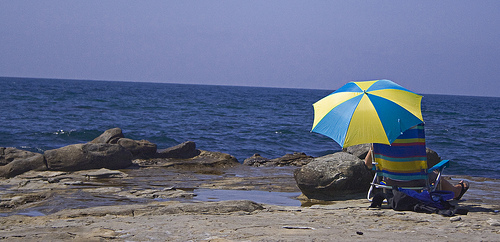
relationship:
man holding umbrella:
[373, 139, 444, 199] [310, 73, 430, 173]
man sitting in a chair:
[364, 139, 471, 203] [371, 118, 452, 213]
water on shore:
[192, 185, 303, 207] [14, 132, 336, 235]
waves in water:
[26, 83, 167, 125] [179, 88, 297, 141]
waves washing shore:
[26, 83, 167, 125] [0, 127, 500, 241]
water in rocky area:
[192, 185, 303, 207] [4, 127, 383, 236]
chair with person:
[361, 134, 444, 218] [400, 123, 487, 221]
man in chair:
[364, 139, 471, 203] [363, 131, 456, 231]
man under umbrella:
[364, 139, 471, 203] [309, 79, 421, 155]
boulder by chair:
[290, 145, 392, 210] [356, 110, 473, 235]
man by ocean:
[364, 139, 471, 203] [29, 80, 479, 161]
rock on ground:
[237, 152, 271, 167] [78, 116, 276, 242]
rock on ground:
[237, 152, 271, 167] [221, 137, 284, 181]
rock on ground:
[237, 152, 271, 167] [245, 119, 307, 192]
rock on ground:
[237, 152, 271, 167] [114, 107, 231, 177]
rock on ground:
[237, 152, 271, 167] [168, 134, 239, 194]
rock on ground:
[237, 152, 271, 167] [102, 122, 153, 197]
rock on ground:
[93, 121, 123, 141] [84, 115, 136, 155]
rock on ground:
[237, 152, 271, 167] [43, 122, 161, 185]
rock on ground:
[237, 152, 271, 167] [81, 152, 129, 187]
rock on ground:
[168, 179, 209, 199] [126, 165, 207, 218]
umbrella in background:
[326, 77, 407, 142] [194, 99, 472, 155]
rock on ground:
[237, 152, 271, 167] [123, 196, 305, 221]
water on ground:
[215, 185, 294, 203] [192, 149, 307, 225]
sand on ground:
[133, 193, 483, 242] [242, 215, 323, 234]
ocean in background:
[23, 67, 298, 149] [44, 164, 297, 207]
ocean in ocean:
[0, 75, 500, 178] [52, 105, 274, 187]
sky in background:
[43, 60, 409, 89] [36, 99, 450, 154]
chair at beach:
[363, 120, 452, 207] [111, 105, 413, 218]